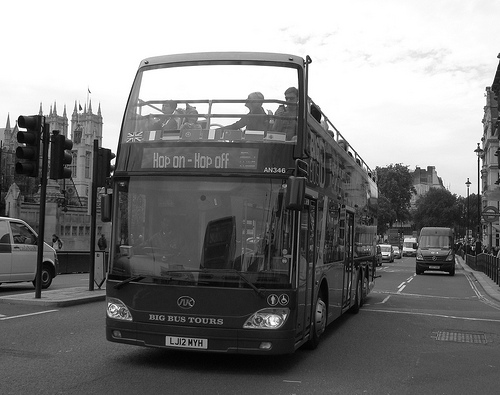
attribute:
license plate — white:
[149, 325, 224, 349]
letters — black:
[157, 329, 180, 349]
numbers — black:
[169, 332, 196, 351]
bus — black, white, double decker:
[112, 49, 337, 369]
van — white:
[8, 224, 44, 284]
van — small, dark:
[401, 221, 465, 301]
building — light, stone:
[34, 110, 109, 199]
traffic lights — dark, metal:
[4, 112, 78, 199]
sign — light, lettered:
[140, 143, 240, 176]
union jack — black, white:
[115, 113, 153, 146]